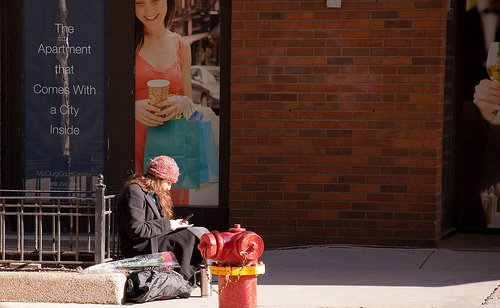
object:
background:
[2, 2, 479, 244]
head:
[143, 156, 180, 193]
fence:
[2, 171, 125, 269]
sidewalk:
[2, 234, 484, 305]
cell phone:
[182, 213, 194, 223]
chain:
[204, 252, 250, 294]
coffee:
[146, 78, 171, 114]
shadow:
[266, 241, 498, 284]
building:
[0, 2, 500, 250]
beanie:
[145, 155, 180, 183]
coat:
[113, 178, 200, 276]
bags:
[141, 94, 201, 190]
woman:
[131, 0, 196, 207]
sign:
[134, 0, 217, 209]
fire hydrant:
[197, 222, 267, 307]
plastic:
[80, 249, 181, 275]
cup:
[145, 79, 170, 112]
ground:
[266, 242, 496, 308]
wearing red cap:
[147, 154, 181, 192]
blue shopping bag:
[184, 94, 220, 184]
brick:
[287, 84, 314, 92]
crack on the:
[419, 250, 435, 270]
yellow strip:
[210, 263, 266, 276]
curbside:
[0, 274, 131, 305]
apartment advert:
[9, 0, 113, 213]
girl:
[116, 154, 206, 292]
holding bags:
[132, 96, 223, 192]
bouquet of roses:
[80, 250, 189, 276]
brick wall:
[232, 6, 456, 247]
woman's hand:
[135, 98, 164, 127]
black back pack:
[124, 268, 195, 303]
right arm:
[116, 181, 171, 241]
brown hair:
[119, 170, 174, 219]